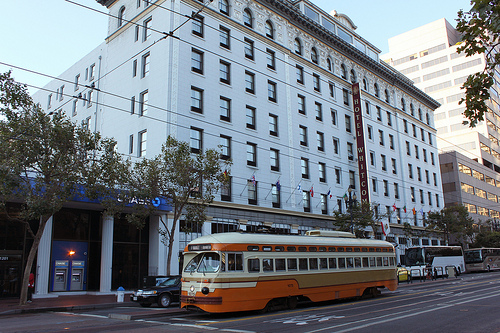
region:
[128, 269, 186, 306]
black car behind orange street bus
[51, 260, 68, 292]
ATM machine next to ATM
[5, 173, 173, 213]
blue overhang over ATM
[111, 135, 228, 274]
tree behind car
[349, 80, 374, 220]
vertical sign on large white building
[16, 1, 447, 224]
building is a hotel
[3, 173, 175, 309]
bank next to hotel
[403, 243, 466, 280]
white bus parked in front of building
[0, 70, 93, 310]
tree to the left of tree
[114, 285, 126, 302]
fire hydrant near car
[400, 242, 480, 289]
the bus is white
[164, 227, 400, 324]
an orange, vintage bus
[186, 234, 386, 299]
orange, brown, and white trolley car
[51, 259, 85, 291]
two cash machines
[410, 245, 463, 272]
white and black bus parked along the street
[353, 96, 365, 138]
sign for a hotel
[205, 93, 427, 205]
white hotel building with many windows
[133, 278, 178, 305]
black car behind the trolley car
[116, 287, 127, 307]
blue and white fire hydrant near the sidewalk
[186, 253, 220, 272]
front window of an orange trolley car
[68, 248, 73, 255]
light above the ATM machines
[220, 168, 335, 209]
flagpoles attached to the white building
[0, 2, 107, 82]
blue of daytime sky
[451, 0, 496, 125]
leaves of tree branch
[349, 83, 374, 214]
vertical sign with white letters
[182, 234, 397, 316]
side of orange and white bus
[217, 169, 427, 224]
row of flags on pole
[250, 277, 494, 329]
white lines on street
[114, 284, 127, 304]
blue and white fire hydrant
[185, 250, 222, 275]
windshield of bus front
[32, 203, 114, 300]
two white columns of building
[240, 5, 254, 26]
arched window of top floor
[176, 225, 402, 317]
Large orange brown and white street car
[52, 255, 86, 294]
Two ATM machines in front of Chase bank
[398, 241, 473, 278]
Tour bus parked on the side of the road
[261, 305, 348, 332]
Instructions painted on the street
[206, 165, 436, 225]
Many flags hanging on the front of the building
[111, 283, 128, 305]
White and blue fire hydrant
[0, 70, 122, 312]
Tree growing through the sidewalk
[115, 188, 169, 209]
Chase sign hidden by the tree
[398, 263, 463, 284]
bicycle rails in the median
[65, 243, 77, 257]
Yellow light above ATMs